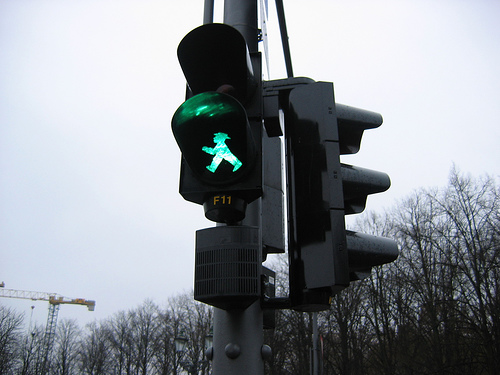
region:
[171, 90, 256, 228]
Traffic sign showing good to walk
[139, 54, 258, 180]
Traffic sign showing good to walk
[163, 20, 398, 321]
Traffic sign showing good to walk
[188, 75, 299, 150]
Traffic sign showing good to walk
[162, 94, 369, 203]
Traffic sign showing good to walk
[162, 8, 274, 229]
Traffic sign showing good to walk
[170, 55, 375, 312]
A black sign post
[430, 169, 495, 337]
A dry tree by the road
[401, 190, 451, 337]
A dry tree by the road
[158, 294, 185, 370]
A dry tree by the road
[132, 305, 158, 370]
A dry tree by the road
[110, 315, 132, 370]
A dry tree by the road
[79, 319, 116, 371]
A dry tree by the road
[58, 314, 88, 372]
A dry tree by the road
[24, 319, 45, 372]
A dry tree by the road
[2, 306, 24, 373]
A dry tree by the road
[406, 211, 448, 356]
tree on side of road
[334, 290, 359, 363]
tree on side of road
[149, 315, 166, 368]
tree on side of road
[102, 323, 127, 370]
tree on side of road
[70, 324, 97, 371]
tree on side of road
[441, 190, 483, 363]
tree on side of road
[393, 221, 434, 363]
tree on side of road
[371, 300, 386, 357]
tree on side of road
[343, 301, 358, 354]
tree on side of road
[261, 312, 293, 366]
tree on side of road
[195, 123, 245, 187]
the man is green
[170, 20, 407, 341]
the light is black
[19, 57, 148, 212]
the sky is cloudy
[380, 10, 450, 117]
the sky is dreary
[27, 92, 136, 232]
the sky is gray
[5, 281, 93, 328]
the crane is behind the trees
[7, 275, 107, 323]
the crane is yellow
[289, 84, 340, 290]
the light is shiney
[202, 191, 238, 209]
f11 is yellow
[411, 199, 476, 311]
the trees are brown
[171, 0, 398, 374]
A metal traffic light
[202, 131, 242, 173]
The symbol is walking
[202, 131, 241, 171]
The symbol is green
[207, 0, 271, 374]
The pole is gray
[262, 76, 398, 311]
The box is dark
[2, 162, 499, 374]
A bunch of dead trees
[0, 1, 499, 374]
The sky is overcast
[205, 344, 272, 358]
Three nubs sticking out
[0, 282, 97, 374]
A big construction crane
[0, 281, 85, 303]
Top of crane is yellow